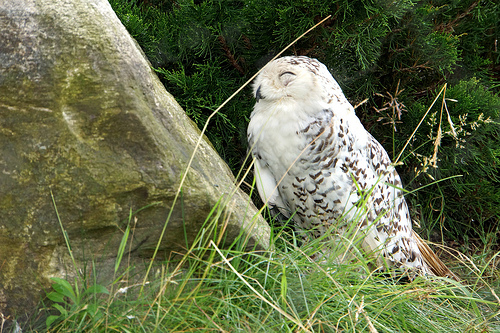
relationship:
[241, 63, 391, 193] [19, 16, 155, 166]
owl near rock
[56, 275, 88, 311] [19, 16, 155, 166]
leaf near rock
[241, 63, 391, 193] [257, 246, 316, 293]
owl in grass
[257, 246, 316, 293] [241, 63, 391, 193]
grass near owl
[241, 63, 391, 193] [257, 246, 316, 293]
owl near grass